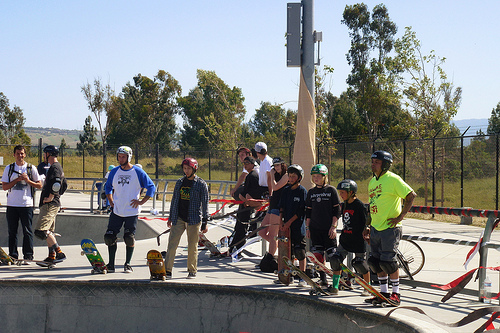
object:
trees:
[77, 74, 120, 184]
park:
[2, 145, 498, 294]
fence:
[1, 137, 499, 219]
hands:
[129, 198, 140, 209]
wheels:
[92, 250, 96, 256]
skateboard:
[79, 235, 109, 274]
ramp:
[1, 281, 418, 333]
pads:
[52, 178, 61, 196]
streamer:
[431, 270, 475, 292]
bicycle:
[364, 231, 427, 280]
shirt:
[366, 169, 412, 232]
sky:
[1, 1, 497, 76]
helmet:
[371, 150, 394, 163]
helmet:
[180, 158, 198, 170]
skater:
[162, 158, 208, 278]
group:
[5, 138, 413, 306]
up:
[79, 238, 95, 244]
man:
[99, 145, 155, 271]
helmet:
[115, 145, 133, 162]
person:
[33, 146, 70, 271]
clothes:
[304, 185, 337, 249]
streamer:
[441, 274, 472, 304]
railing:
[403, 205, 498, 219]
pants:
[164, 217, 202, 279]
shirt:
[104, 163, 158, 219]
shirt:
[258, 154, 274, 188]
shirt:
[274, 184, 308, 242]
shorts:
[34, 202, 59, 234]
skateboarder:
[101, 143, 159, 273]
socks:
[330, 274, 341, 290]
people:
[360, 148, 418, 309]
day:
[2, 1, 488, 136]